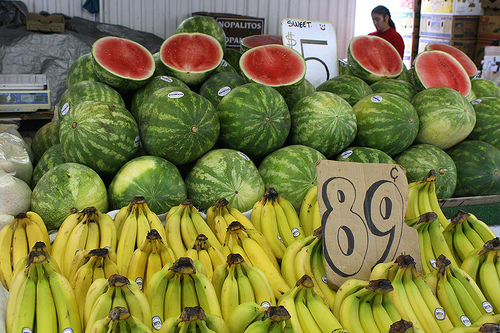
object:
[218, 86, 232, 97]
sticker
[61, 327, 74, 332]
sticker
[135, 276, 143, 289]
sticker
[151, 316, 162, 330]
sticker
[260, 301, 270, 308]
sticker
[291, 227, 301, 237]
sticker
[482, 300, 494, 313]
sticker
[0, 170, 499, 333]
banana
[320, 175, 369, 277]
hand drawn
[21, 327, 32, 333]
sticker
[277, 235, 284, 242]
sticker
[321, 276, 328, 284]
sticker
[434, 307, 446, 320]
sticker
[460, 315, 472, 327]
sticker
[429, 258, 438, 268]
sticker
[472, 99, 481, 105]
sticker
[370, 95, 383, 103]
sticker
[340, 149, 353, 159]
sticker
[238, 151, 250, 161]
sticker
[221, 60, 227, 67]
sticker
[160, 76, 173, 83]
sticker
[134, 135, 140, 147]
sticker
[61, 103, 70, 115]
sticker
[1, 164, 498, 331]
banana pile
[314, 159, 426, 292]
sign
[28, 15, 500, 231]
watermelon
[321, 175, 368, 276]
number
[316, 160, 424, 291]
cardboard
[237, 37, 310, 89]
fruit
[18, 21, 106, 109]
tarp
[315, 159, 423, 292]
cardoard piece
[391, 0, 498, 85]
boxes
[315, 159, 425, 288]
cardboard sign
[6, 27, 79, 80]
canvas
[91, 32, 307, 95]
three watermons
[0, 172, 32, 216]
cantaloupe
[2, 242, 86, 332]
banana bunch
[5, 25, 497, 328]
fruit stand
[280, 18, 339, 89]
sign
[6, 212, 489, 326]
ripe bananas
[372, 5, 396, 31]
hair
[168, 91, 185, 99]
sticker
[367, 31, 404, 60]
red shirt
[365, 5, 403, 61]
man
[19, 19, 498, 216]
pile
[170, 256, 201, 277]
end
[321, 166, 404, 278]
89 cents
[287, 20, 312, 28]
sweet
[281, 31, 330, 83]
$5